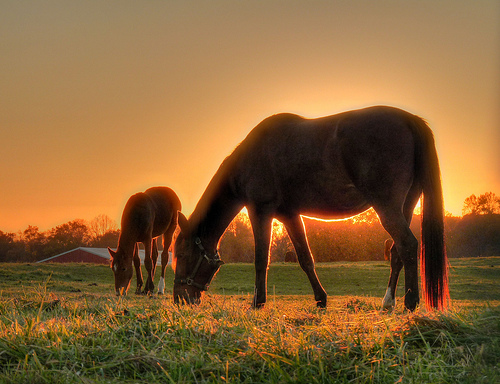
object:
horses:
[171, 104, 453, 312]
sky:
[6, 3, 494, 230]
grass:
[1, 307, 494, 379]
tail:
[410, 124, 448, 312]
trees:
[453, 190, 499, 252]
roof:
[39, 247, 175, 259]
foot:
[382, 290, 395, 316]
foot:
[157, 279, 167, 294]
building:
[41, 238, 177, 265]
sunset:
[418, 144, 476, 217]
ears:
[177, 211, 193, 240]